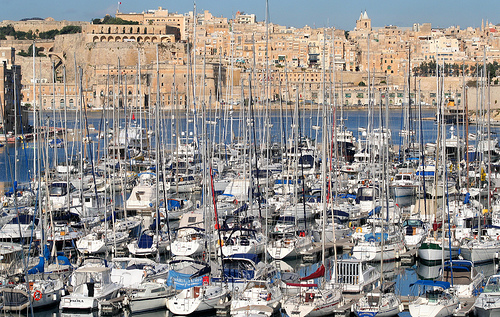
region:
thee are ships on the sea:
[111, 123, 451, 309]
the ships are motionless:
[41, 117, 453, 314]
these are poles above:
[188, 72, 366, 172]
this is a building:
[112, 13, 172, 46]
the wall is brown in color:
[115, 20, 148, 37]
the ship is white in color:
[421, 245, 437, 259]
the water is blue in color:
[388, 106, 405, 123]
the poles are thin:
[151, 59, 390, 161]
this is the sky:
[396, 3, 429, 18]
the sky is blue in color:
[400, 3, 435, 20]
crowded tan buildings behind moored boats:
[12, 6, 493, 307]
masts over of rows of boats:
[2, 20, 489, 300]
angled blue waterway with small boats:
[0, 106, 499, 176]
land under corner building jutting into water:
[2, 56, 67, 143]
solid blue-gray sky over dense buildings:
[0, 1, 495, 57]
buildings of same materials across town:
[5, 20, 491, 100]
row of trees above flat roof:
[410, 25, 495, 95]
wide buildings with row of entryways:
[80, 20, 175, 45]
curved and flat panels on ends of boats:
[37, 156, 484, 306]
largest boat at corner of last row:
[106, 110, 167, 185]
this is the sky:
[376, 2, 440, 26]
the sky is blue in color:
[375, 5, 402, 18]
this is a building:
[96, 22, 172, 57]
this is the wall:
[105, 47, 134, 61]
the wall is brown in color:
[100, 46, 129, 61]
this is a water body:
[9, 142, 36, 172]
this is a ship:
[170, 290, 215, 314]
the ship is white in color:
[142, 295, 160, 313]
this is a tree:
[16, 25, 32, 43]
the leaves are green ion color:
[13, 24, 21, 44]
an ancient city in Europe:
[1, 0, 499, 111]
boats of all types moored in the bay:
[0, 84, 498, 315]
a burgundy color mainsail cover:
[300, 265, 327, 280]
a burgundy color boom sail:
[285, 281, 319, 287]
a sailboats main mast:
[31, 31, 41, 195]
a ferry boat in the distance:
[435, 99, 472, 126]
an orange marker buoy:
[130, 110, 136, 120]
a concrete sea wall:
[0, 124, 70, 142]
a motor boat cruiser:
[60, 254, 122, 310]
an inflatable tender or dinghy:
[1, 287, 33, 312]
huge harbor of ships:
[0, 55, 468, 277]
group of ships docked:
[60, 80, 441, 315]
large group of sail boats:
[51, 65, 458, 314]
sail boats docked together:
[1, 83, 468, 314]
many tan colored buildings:
[34, 0, 416, 102]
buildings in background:
[0, 2, 372, 127]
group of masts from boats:
[0, 29, 474, 199]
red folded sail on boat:
[288, 262, 329, 280]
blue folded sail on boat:
[30, 253, 49, 273]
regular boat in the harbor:
[58, 258, 115, 314]